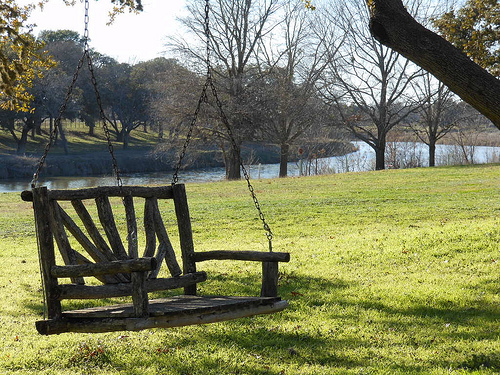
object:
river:
[0, 137, 499, 192]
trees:
[0, 1, 60, 115]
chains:
[31, 0, 122, 189]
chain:
[172, 0, 273, 250]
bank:
[0, 139, 357, 176]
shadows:
[301, 277, 418, 374]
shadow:
[470, 272, 500, 375]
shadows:
[43, 267, 335, 324]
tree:
[414, 86, 447, 169]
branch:
[366, 0, 499, 127]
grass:
[339, 291, 481, 364]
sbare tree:
[184, 0, 321, 175]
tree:
[40, 62, 67, 138]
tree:
[96, 72, 150, 147]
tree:
[136, 59, 183, 139]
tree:
[470, 0, 500, 59]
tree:
[308, 0, 445, 170]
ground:
[147, 171, 207, 372]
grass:
[0, 256, 35, 373]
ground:
[2, 190, 26, 355]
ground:
[354, 247, 470, 372]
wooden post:
[22, 182, 186, 200]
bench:
[20, 182, 289, 330]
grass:
[319, 215, 387, 259]